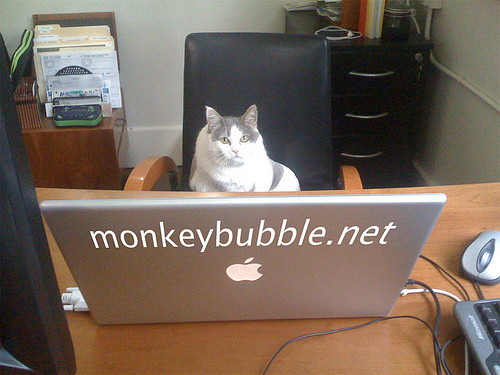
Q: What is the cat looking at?
A: Laptop.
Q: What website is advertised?
A: Monkeybubble.net.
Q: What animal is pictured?
A: Cat.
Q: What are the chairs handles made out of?
A: Wood.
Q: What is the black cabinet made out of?
A: Metal.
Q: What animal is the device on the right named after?
A: Mouse.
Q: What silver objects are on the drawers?
A: Handles.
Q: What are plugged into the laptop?
A: Wires.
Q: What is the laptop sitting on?
A: Desk.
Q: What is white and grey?
A: Cat.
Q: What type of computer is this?
A: Laptop.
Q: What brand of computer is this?
A: Apple.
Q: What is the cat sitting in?
A: Chair.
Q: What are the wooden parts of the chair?
A: Armrests.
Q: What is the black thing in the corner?
A: File cabinet.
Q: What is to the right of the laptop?
A: Mouse.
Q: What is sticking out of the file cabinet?
A: Keys.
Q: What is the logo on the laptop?
A: Apple.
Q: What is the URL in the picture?
A: Monkeybubble.net.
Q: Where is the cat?
A: On the chair.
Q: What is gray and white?
A: The cat.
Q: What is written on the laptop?
A: Monkeybubble.net.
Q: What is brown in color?
A: The table.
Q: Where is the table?
A: Next to the cat.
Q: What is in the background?
A: The wall.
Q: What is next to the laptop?
A: A mouse.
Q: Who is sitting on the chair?
A: Cat.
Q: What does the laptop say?
A: Monkeybubble.net.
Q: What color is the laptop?
A: Silver.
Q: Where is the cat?
A: On the chair.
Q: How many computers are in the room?
A: 1.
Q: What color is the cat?
A: White and gray.